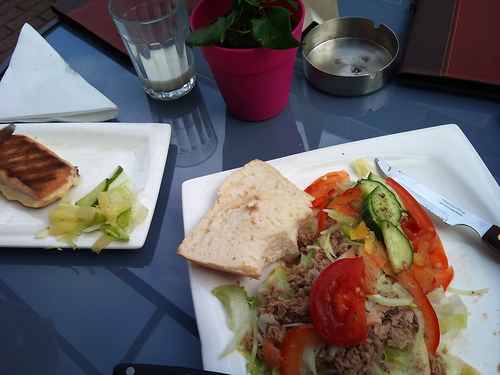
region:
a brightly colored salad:
[176, 163, 490, 374]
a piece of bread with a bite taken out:
[176, 155, 321, 284]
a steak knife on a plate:
[370, 151, 498, 259]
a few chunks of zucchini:
[355, 177, 417, 277]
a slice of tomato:
[303, 252, 373, 354]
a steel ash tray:
[300, 13, 404, 97]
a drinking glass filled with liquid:
[103, 1, 210, 110]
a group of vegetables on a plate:
[40, 167, 150, 257]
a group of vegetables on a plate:
[310, 172, 457, 364]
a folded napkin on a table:
[4, 18, 121, 118]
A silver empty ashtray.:
[298, 17, 400, 97]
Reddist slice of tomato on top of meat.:
[309, 254, 370, 346]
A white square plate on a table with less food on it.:
[0, 119, 170, 249]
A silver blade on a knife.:
[373, 156, 492, 239]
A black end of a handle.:
[478, 221, 498, 248]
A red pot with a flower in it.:
[190, 4, 302, 121]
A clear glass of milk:
[107, 2, 196, 99]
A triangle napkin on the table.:
[0, 29, 120, 123]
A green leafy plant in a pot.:
[181, 4, 306, 49]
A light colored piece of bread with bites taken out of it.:
[176, 159, 313, 279]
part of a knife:
[374, 158, 497, 254]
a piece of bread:
[170, 162, 312, 283]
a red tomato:
[313, 260, 365, 345]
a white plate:
[2, 111, 173, 253]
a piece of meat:
[0, 127, 87, 217]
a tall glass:
[107, 1, 195, 98]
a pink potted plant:
[190, 2, 308, 128]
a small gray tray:
[295, 8, 403, 98]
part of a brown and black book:
[383, 3, 498, 105]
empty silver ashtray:
[301, 14, 400, 95]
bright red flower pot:
[186, 0, 305, 124]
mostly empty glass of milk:
[108, 0, 195, 100]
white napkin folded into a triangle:
[1, 22, 118, 124]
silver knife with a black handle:
[376, 155, 499, 253]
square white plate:
[182, 124, 499, 373]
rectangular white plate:
[0, 121, 171, 248]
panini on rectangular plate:
[0, 135, 79, 208]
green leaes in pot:
[189, 3, 306, 124]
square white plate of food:
[181, 122, 496, 373]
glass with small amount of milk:
[108, 1, 193, 100]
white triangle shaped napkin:
[0, 19, 115, 119]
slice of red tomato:
[308, 257, 370, 346]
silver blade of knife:
[374, 157, 498, 241]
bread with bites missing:
[178, 155, 316, 281]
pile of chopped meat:
[266, 248, 412, 367]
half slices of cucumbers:
[362, 176, 413, 271]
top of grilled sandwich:
[0, 135, 71, 211]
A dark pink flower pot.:
[191, 0, 304, 122]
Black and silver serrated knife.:
[375, 157, 499, 252]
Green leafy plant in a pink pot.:
[186, 1, 307, 49]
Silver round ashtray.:
[301, 16, 399, 98]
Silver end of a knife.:
[375, 159, 493, 237]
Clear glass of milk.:
[107, 1, 196, 102]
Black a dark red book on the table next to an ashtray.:
[397, 0, 497, 93]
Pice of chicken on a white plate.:
[1, 134, 81, 210]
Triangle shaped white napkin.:
[1, 21, 118, 123]